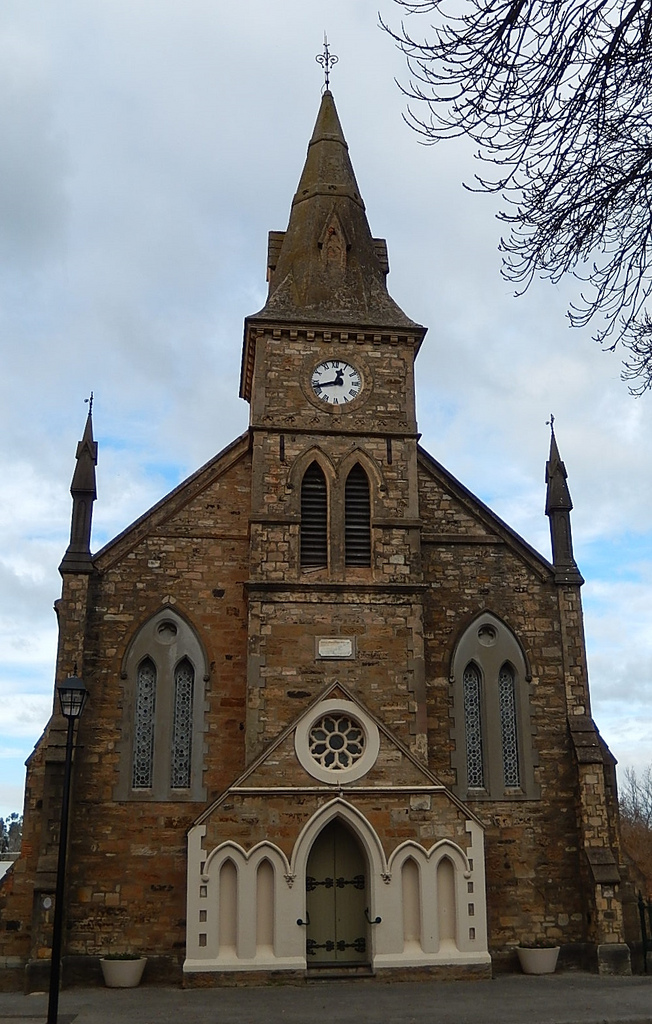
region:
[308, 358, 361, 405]
white clock face with black numerals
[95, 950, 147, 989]
plant in a tan colored planter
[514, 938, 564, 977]
plant in a tan colored planter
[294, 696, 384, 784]
circular window with Gothic style decoration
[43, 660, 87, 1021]
old fashion style lamp post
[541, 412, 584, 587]
decorative turret with a weather vane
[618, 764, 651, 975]
trees with orange leaves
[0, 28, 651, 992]
large brown stone church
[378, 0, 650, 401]
leafless top of a tree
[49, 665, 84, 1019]
Street light is not aglow.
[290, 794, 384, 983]
The door is closed.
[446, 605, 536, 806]
Stained glass window.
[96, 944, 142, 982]
Plants in a pot.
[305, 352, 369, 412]
Clock on church tower.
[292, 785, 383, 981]
The doors are secured.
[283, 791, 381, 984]
Front entrance to the church.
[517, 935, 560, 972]
Potted outdoor plants.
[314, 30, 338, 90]
Weather vane on steeple.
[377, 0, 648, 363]
Tree has no leaves.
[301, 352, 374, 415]
clock on the building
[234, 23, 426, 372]
steeple on the building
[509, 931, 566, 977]
Planter beside the wall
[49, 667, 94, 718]
Light on top of the pole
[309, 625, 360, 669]
Plaque on the building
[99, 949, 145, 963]
Plants in the pot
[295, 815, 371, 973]
Doors to the building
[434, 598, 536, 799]
Window in the building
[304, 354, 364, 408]
roman numerals on the clock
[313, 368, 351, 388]
black hands on the clock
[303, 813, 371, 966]
Door at the front of the church.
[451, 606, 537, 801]
Right side church window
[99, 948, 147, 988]
Potted fern in front of the church.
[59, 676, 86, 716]
The top part of the street light.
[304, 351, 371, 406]
The clock atop of the church.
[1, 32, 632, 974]
Big brick church with clock tower.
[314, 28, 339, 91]
Decorative metal top of the church.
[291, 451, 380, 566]
Wooden window shutters of the church.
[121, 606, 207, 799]
The left side window of the church.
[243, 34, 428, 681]
Clock tower that is the top of the church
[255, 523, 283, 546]
brown brick on building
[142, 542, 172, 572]
brown brick on building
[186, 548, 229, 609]
brown brick on building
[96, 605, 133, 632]
brown brick on building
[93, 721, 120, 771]
brown brick on building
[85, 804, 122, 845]
brown brick on building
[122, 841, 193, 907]
brown brick on building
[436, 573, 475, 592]
brown brick on building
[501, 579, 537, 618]
brown brick on building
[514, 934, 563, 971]
flower pot in front of building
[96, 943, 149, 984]
flower pot in front of building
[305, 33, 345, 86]
awning on top of the tower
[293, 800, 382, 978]
arched doorway on the building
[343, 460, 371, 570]
shutters on the window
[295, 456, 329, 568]
shutters on the window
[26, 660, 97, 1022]
street lamp on the sidewalk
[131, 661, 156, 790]
A window on a building.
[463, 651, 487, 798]
A window on a building.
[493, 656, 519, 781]
A window on a building.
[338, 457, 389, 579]
A window on a building.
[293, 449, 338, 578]
A window on a building.